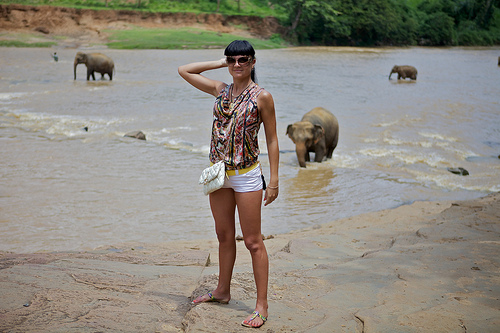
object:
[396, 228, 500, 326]
ground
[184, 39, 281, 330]
woman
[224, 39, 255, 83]
hair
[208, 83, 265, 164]
shirt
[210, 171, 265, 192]
shorts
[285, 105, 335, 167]
elephant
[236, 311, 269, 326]
sandals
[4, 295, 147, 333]
sand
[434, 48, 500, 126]
water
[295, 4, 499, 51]
trees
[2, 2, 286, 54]
bank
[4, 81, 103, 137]
wave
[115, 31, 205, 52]
grass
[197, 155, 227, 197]
handbag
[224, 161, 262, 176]
belt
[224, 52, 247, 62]
sunglasses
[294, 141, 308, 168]
trunk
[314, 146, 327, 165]
leg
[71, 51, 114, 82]
elephant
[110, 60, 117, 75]
tail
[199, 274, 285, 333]
rock